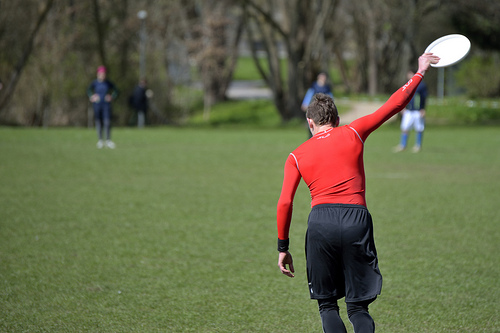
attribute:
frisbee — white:
[417, 32, 472, 69]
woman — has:
[86, 60, 122, 152]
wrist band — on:
[277, 236, 289, 251]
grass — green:
[1, 115, 497, 331]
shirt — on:
[273, 73, 424, 245]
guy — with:
[267, 87, 428, 331]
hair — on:
[303, 92, 340, 121]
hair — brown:
[293, 86, 368, 149]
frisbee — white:
[406, 10, 493, 80]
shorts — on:
[303, 203, 380, 298]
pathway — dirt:
[336, 90, 401, 126]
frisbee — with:
[412, 22, 479, 75]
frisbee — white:
[427, 37, 474, 71]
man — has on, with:
[273, 50, 444, 331]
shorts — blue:
[303, 203, 385, 307]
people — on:
[96, 60, 109, 153]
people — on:
[130, 67, 151, 138]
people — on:
[401, 67, 423, 156]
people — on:
[309, 60, 329, 111]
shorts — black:
[298, 206, 398, 316]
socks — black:
[295, 303, 398, 331]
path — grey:
[212, 76, 289, 114]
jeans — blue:
[89, 105, 125, 148]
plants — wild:
[422, 92, 485, 131]